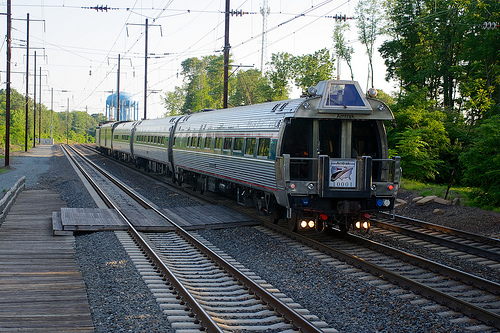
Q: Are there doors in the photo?
A: Yes, there is a door.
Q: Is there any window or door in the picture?
A: Yes, there is a door.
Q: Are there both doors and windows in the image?
A: Yes, there are both a door and a window.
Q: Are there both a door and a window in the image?
A: Yes, there are both a door and a window.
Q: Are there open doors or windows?
A: Yes, there is an open door.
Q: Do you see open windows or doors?
A: Yes, there is an open door.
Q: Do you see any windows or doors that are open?
A: Yes, the door is open.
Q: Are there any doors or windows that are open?
A: Yes, the door is open.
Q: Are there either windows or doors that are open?
A: Yes, the door is open.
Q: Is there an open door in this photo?
A: Yes, there is an open door.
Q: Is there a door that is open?
A: Yes, there is a door that is open.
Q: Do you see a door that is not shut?
A: Yes, there is a open door.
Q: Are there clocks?
A: No, there are no clocks.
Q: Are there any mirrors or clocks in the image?
A: No, there are no clocks or mirrors.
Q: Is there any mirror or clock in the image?
A: No, there are no clocks or mirrors.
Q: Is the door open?
A: Yes, the door is open.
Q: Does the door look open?
A: Yes, the door is open.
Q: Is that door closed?
A: No, the door is open.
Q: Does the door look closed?
A: No, the door is open.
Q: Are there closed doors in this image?
A: No, there is a door but it is open.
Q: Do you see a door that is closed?
A: No, there is a door but it is open.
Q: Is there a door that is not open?
A: No, there is a door but it is open.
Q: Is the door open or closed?
A: The door is open.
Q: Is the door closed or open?
A: The door is open.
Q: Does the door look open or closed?
A: The door is open.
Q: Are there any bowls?
A: No, there are no bowls.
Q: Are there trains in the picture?
A: Yes, there is a train.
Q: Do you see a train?
A: Yes, there is a train.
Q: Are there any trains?
A: Yes, there is a train.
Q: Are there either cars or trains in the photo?
A: Yes, there is a train.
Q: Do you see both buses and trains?
A: No, there is a train but no buses.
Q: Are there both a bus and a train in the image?
A: No, there is a train but no buses.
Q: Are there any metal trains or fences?
A: Yes, there is a metal train.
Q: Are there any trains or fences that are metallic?
A: Yes, the train is metallic.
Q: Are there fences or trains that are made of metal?
A: Yes, the train is made of metal.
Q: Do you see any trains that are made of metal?
A: Yes, there is a train that is made of metal.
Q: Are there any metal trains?
A: Yes, there is a train that is made of metal.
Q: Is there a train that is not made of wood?
A: Yes, there is a train that is made of metal.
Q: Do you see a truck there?
A: No, there are no trucks.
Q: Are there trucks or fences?
A: No, there are no trucks or fences.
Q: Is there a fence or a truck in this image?
A: No, there are no trucks or fences.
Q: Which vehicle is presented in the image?
A: The vehicle is a train.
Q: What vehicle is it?
A: The vehicle is a train.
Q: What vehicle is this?
A: This is a train.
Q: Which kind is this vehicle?
A: This is a train.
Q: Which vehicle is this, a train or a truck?
A: This is a train.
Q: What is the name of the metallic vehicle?
A: The vehicle is a train.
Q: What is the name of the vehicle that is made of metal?
A: The vehicle is a train.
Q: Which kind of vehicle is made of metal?
A: The vehicle is a train.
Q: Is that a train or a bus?
A: That is a train.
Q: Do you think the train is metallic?
A: Yes, the train is metallic.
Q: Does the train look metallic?
A: Yes, the train is metallic.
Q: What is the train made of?
A: The train is made of metal.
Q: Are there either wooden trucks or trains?
A: No, there is a train but it is metallic.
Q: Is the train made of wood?
A: No, the train is made of metal.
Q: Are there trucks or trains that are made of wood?
A: No, there is a train but it is made of metal.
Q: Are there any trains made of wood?
A: No, there is a train but it is made of metal.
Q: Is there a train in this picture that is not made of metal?
A: No, there is a train but it is made of metal.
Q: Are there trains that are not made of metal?
A: No, there is a train but it is made of metal.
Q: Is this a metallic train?
A: Yes, this is a metallic train.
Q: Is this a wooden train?
A: No, this is a metallic train.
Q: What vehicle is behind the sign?
A: The vehicle is a train.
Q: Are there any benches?
A: No, there are no benches.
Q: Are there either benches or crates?
A: No, there are no benches or crates.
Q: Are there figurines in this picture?
A: No, there are no figurines.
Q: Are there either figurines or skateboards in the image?
A: No, there are no figurines or skateboards.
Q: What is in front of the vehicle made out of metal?
A: The sign is in front of the train.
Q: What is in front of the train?
A: The sign is in front of the train.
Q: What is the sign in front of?
A: The sign is in front of the train.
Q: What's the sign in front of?
A: The sign is in front of the train.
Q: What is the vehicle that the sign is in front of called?
A: The vehicle is a train.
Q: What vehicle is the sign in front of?
A: The sign is in front of the train.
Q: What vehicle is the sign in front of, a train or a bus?
A: The sign is in front of a train.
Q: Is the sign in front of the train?
A: Yes, the sign is in front of the train.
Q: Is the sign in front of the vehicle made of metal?
A: Yes, the sign is in front of the train.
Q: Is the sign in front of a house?
A: No, the sign is in front of the train.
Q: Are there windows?
A: Yes, there is a window.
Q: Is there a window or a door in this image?
A: Yes, there is a window.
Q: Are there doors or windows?
A: Yes, there is a window.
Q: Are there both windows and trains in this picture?
A: Yes, there are both a window and a train.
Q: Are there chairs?
A: No, there are no chairs.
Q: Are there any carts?
A: No, there are no carts.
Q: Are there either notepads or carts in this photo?
A: No, there are no carts or notepads.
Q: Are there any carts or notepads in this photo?
A: No, there are no carts or notepads.